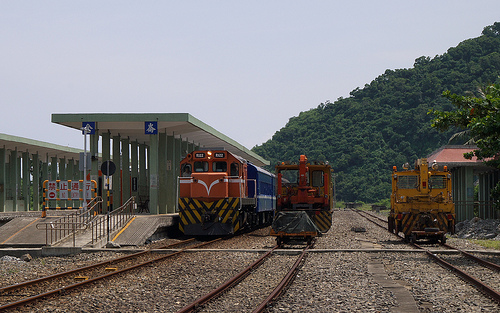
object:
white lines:
[173, 179, 245, 195]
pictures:
[144, 121, 158, 135]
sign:
[81, 121, 96, 135]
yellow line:
[110, 214, 138, 243]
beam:
[146, 134, 160, 212]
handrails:
[32, 194, 138, 248]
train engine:
[172, 147, 249, 240]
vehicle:
[386, 159, 457, 241]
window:
[193, 160, 208, 173]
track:
[350, 212, 500, 313]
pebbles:
[274, 191, 500, 313]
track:
[175, 241, 316, 313]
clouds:
[121, 3, 336, 103]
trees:
[243, 22, 499, 200]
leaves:
[432, 77, 498, 155]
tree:
[432, 83, 497, 209]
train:
[176, 149, 289, 236]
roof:
[426, 142, 496, 165]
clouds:
[1, 0, 497, 150]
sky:
[1, 0, 498, 154]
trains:
[265, 149, 337, 245]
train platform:
[0, 111, 253, 264]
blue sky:
[0, 0, 500, 147]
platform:
[0, 209, 171, 244]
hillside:
[238, 24, 500, 201]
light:
[204, 150, 214, 159]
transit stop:
[0, 112, 270, 238]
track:
[2, 212, 264, 313]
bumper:
[179, 198, 234, 234]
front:
[174, 148, 244, 237]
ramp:
[0, 210, 164, 247]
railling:
[37, 195, 136, 245]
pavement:
[0, 205, 178, 255]